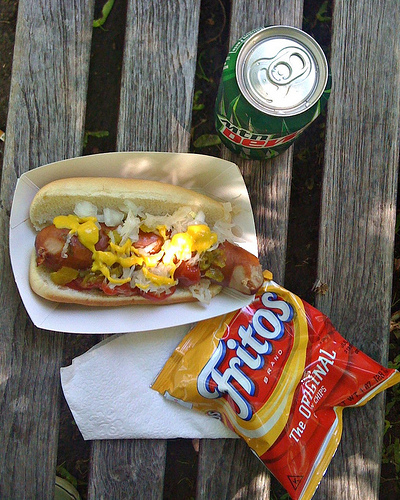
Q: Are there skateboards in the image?
A: No, there are no skateboards.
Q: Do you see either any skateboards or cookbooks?
A: No, there are no skateboards or cookbooks.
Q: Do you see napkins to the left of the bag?
A: Yes, there is a napkin to the left of the bag.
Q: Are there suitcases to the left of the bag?
A: No, there is a napkin to the left of the bag.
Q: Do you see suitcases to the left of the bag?
A: No, there is a napkin to the left of the bag.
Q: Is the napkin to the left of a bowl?
A: No, the napkin is to the left of the bag.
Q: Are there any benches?
A: Yes, there is a bench.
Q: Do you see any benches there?
A: Yes, there is a bench.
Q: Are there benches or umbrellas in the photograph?
A: Yes, there is a bench.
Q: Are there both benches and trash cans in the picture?
A: No, there is a bench but no trash cans.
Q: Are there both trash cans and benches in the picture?
A: No, there is a bench but no trash cans.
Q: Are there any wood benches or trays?
A: Yes, there is a wood bench.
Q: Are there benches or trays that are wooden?
A: Yes, the bench is wooden.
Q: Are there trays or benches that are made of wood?
A: Yes, the bench is made of wood.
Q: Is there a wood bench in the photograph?
A: Yes, there is a wood bench.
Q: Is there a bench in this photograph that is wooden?
A: Yes, there is a bench that is wooden.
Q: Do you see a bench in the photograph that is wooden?
A: Yes, there is a bench that is wooden.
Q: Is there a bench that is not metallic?
A: Yes, there is a wooden bench.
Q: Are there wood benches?
A: Yes, there is a bench that is made of wood.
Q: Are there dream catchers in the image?
A: No, there are no dream catchers.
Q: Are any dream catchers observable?
A: No, there are no dream catchers.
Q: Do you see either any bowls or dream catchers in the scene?
A: No, there are no dream catchers or bowls.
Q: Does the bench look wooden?
A: Yes, the bench is wooden.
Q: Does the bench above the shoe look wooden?
A: Yes, the bench is wooden.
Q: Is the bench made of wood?
A: Yes, the bench is made of wood.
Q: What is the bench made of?
A: The bench is made of wood.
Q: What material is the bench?
A: The bench is made of wood.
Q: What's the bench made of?
A: The bench is made of wood.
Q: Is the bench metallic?
A: No, the bench is wooden.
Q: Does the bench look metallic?
A: No, the bench is wooden.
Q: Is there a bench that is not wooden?
A: No, there is a bench but it is wooden.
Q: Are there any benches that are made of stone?
A: No, there is a bench but it is made of wood.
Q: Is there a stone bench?
A: No, there is a bench but it is made of wood.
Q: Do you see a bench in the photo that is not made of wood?
A: No, there is a bench but it is made of wood.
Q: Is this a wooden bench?
A: Yes, this is a wooden bench.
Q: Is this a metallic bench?
A: No, this is a wooden bench.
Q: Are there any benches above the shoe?
A: Yes, there is a bench above the shoe.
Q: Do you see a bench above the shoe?
A: Yes, there is a bench above the shoe.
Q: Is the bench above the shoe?
A: Yes, the bench is above the shoe.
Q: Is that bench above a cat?
A: No, the bench is above the shoe.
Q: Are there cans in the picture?
A: Yes, there is a can.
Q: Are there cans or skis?
A: Yes, there is a can.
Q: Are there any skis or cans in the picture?
A: Yes, there is a can.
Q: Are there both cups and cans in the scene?
A: No, there is a can but no cups.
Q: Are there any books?
A: No, there are no books.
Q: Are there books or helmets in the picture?
A: No, there are no books or helmets.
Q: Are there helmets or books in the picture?
A: No, there are no books or helmets.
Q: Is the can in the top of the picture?
A: Yes, the can is in the top of the image.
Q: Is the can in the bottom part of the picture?
A: No, the can is in the top of the image.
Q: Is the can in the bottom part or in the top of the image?
A: The can is in the top of the image.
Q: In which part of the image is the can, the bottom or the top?
A: The can is in the top of the image.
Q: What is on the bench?
A: The can is on the bench.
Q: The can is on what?
A: The can is on the bench.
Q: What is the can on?
A: The can is on the bench.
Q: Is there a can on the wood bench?
A: Yes, there is a can on the bench.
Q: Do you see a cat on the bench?
A: No, there is a can on the bench.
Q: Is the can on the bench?
A: Yes, the can is on the bench.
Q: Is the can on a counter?
A: No, the can is on the bench.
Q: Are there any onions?
A: Yes, there are onions.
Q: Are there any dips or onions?
A: Yes, there are onions.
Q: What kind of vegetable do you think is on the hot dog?
A: The vegetables are onions.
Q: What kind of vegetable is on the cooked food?
A: The vegetables are onions.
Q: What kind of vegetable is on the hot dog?
A: The vegetables are onions.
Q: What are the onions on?
A: The onions are on the hot dog.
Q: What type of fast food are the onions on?
A: The onions are on the hot dog.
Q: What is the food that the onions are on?
A: The food is a hot dog.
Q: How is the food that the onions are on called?
A: The food is a hot dog.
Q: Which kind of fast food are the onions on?
A: The onions are on the hot dog.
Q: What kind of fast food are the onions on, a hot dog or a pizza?
A: The onions are on a hot dog.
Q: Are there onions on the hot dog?
A: Yes, there are onions on the hot dog.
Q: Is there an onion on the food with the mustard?
A: Yes, there are onions on the hot dog.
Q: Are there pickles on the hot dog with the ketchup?
A: No, there are onions on the hot dog.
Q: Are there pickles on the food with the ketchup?
A: No, there are onions on the hot dog.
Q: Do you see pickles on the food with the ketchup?
A: No, there are onions on the hot dog.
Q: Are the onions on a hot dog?
A: Yes, the onions are on a hot dog.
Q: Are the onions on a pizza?
A: No, the onions are on a hot dog.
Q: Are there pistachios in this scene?
A: No, there are no pistachios.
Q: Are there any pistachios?
A: No, there are no pistachios.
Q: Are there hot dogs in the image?
A: Yes, there is a hot dog.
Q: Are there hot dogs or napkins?
A: Yes, there is a hot dog.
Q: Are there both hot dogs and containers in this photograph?
A: Yes, there are both a hot dog and a container.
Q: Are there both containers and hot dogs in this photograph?
A: Yes, there are both a hot dog and a container.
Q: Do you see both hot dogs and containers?
A: Yes, there are both a hot dog and a container.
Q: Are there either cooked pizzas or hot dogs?
A: Yes, there is a cooked hot dog.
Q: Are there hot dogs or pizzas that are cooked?
A: Yes, the hot dog is cooked.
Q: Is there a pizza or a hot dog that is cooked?
A: Yes, the hot dog is cooked.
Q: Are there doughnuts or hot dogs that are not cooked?
A: No, there is a hot dog but it is cooked.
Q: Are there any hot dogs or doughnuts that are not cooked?
A: No, there is a hot dog but it is cooked.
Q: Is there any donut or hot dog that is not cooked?
A: No, there is a hot dog but it is cooked.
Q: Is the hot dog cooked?
A: Yes, the hot dog is cooked.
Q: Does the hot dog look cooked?
A: Yes, the hot dog is cooked.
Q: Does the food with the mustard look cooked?
A: Yes, the hot dog is cooked.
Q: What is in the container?
A: The hot dog is in the container.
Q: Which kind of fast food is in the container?
A: The food is a hot dog.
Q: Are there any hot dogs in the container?
A: Yes, there is a hot dog in the container.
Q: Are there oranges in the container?
A: No, there is a hot dog in the container.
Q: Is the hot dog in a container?
A: Yes, the hot dog is in a container.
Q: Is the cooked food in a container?
A: Yes, the hot dog is in a container.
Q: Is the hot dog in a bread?
A: No, the hot dog is in a container.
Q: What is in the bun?
A: The hot dog is in the bun.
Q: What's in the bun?
A: The hot dog is in the bun.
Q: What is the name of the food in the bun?
A: The food is a hot dog.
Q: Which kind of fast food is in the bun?
A: The food is a hot dog.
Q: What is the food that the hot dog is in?
A: The food is a bun.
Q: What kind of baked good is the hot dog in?
A: The hot dog is in the bun.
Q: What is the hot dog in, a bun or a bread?
A: The hot dog is in a bun.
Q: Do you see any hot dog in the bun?
A: Yes, there is a hot dog in the bun.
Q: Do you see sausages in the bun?
A: No, there is a hot dog in the bun.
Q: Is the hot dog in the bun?
A: Yes, the hot dog is in the bun.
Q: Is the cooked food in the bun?
A: Yes, the hot dog is in the bun.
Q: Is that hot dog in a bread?
A: No, the hot dog is in the bun.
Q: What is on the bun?
A: The hot dog is on the bun.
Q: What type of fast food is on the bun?
A: The food is a hot dog.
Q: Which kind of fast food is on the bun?
A: The food is a hot dog.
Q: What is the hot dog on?
A: The hot dog is on the bun.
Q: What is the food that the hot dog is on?
A: The food is a bun.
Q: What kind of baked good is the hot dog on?
A: The hot dog is on the bun.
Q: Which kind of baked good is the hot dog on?
A: The hot dog is on the bun.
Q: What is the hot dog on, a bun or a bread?
A: The hot dog is on a bun.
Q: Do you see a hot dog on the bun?
A: Yes, there is a hot dog on the bun.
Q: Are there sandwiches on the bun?
A: No, there is a hot dog on the bun.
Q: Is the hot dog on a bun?
A: Yes, the hot dog is on a bun.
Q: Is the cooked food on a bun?
A: Yes, the hot dog is on a bun.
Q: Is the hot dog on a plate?
A: No, the hot dog is on a bun.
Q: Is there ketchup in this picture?
A: Yes, there is ketchup.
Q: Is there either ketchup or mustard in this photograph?
A: Yes, there is ketchup.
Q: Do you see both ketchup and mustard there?
A: Yes, there are both ketchup and mustard.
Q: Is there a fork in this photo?
A: No, there are no forks.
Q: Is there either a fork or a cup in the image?
A: No, there are no forks or cups.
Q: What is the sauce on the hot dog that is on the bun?
A: The sauce is ketchup.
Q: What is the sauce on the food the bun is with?
A: The sauce is ketchup.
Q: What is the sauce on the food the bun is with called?
A: The sauce is ketchup.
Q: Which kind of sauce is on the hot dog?
A: The sauce is ketchup.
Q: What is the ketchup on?
A: The ketchup is on the hot dog.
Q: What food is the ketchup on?
A: The ketchup is on the hot dog.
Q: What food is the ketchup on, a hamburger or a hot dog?
A: The ketchup is on a hot dog.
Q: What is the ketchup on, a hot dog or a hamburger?
A: The ketchup is on a hot dog.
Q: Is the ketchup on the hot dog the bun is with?
A: Yes, the ketchup is on the hot dog.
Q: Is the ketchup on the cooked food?
A: Yes, the ketchup is on the hot dog.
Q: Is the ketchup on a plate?
A: No, the ketchup is on the hot dog.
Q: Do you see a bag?
A: Yes, there is a bag.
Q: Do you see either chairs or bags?
A: Yes, there is a bag.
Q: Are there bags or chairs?
A: Yes, there is a bag.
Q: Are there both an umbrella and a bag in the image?
A: No, there is a bag but no umbrellas.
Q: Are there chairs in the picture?
A: No, there are no chairs.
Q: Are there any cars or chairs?
A: No, there are no chairs or cars.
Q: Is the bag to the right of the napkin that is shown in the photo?
A: Yes, the bag is to the right of the napkin.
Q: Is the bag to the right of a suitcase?
A: No, the bag is to the right of the napkin.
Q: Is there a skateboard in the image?
A: No, there are no skateboards.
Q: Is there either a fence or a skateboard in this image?
A: No, there are no skateboards or fences.